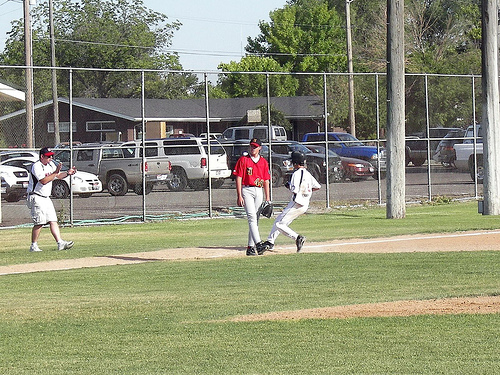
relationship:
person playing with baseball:
[235, 140, 269, 257] [260, 203, 275, 220]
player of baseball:
[235, 140, 269, 257] [260, 203, 275, 220]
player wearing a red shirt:
[235, 140, 269, 257] [232, 151, 274, 190]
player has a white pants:
[235, 140, 269, 257] [239, 185, 266, 246]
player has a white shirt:
[269, 151, 320, 250] [285, 169, 321, 207]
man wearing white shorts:
[25, 145, 79, 251] [28, 191, 62, 227]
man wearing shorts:
[25, 145, 79, 251] [28, 191, 62, 227]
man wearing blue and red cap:
[25, 145, 79, 251] [38, 145, 55, 157]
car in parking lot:
[123, 143, 233, 189] [1, 120, 490, 221]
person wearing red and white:
[235, 137, 269, 258] [235, 136, 271, 258]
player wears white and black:
[269, 151, 320, 250] [270, 155, 318, 252]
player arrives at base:
[269, 151, 320, 250] [237, 244, 295, 257]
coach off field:
[25, 145, 79, 251] [13, 198, 494, 314]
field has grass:
[13, 198, 494, 314] [21, 285, 198, 373]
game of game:
[224, 133, 318, 263] [228, 137, 322, 258]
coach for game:
[25, 145, 79, 251] [228, 137, 322, 258]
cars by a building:
[10, 92, 352, 150] [5, 98, 357, 149]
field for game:
[13, 198, 494, 314] [228, 137, 322, 258]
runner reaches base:
[269, 151, 320, 250] [237, 244, 295, 257]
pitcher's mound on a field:
[152, 242, 224, 263] [13, 198, 494, 314]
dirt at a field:
[405, 241, 459, 251] [13, 198, 494, 314]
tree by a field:
[7, 4, 194, 96] [13, 198, 494, 314]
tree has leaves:
[7, 4, 194, 96] [108, 12, 150, 47]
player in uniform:
[269, 151, 320, 250] [234, 152, 270, 242]